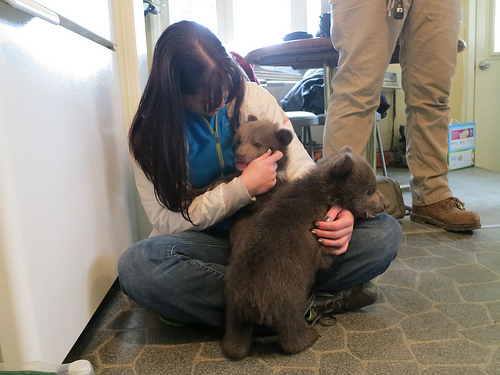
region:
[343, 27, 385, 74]
part of a trouser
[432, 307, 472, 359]
part of the floor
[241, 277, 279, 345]
back of a bear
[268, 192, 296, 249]
back of a bear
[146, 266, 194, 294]
part of a jeans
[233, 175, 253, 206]
edge of a sleeve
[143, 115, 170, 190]
hair of a girl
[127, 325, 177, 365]
part of a shade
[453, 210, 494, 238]
part of a shoe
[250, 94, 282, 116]
part of a jumper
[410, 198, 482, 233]
a brown boot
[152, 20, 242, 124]
a lady with brown hair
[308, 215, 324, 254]
fingernail polish on the lady's nails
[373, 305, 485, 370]
marble design on the floor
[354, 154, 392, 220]
baby bears face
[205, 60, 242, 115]
brown bangs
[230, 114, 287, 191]
a lady touching the bears' face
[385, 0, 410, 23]
keys on the man's pants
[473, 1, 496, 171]
silver doorknob on the door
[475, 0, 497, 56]
window on the door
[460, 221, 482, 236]
part of a shoe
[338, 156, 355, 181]
right ear of a bear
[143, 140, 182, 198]
hair of a girl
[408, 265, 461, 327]
part of the floor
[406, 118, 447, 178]
part of a trouser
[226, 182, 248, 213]
part of a sleeve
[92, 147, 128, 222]
part of a shade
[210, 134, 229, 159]
part of a zip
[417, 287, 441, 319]
part of some lines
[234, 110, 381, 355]
Two bear cubs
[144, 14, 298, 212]
A woman holding two bear cubs.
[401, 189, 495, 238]
A work boot.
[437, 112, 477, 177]
A box of kitty litter.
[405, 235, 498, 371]
A stone looking floor.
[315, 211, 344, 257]
Silvery nail polish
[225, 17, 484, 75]
Small table.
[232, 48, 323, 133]
A chair.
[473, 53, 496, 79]
A door knob.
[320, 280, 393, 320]
Brown boots.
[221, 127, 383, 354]
Two bears are playing.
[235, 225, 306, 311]
Bear is brown color.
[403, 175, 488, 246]
Man shoe is brown color.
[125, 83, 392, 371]
Lady is sitting in the floor.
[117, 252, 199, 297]
Lady is wearing blue jeans.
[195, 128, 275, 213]
One bear is sitting in the woman lap.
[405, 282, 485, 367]
Floor is grey color.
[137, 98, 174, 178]
Woman hair is black color.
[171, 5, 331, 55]
Sunlight passes through the window.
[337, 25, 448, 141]
Man is wearing tan color pant.